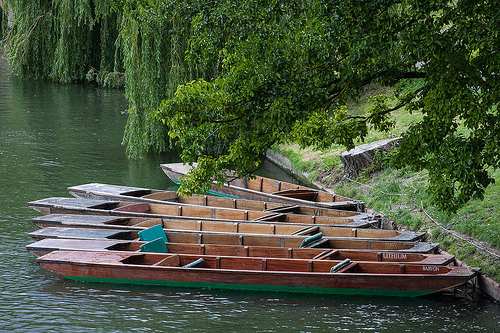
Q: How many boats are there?
A: 7.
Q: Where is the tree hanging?
A: Behind the boats.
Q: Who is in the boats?
A: No one.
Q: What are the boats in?
A: Water.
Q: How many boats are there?
A: Seven.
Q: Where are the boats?
A: In the water.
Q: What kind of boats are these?
A: Rowing.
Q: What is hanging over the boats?
A: A tree branch.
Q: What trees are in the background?
A: Weeping willows.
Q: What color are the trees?
A: Green.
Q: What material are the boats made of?
A: Wood.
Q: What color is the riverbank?
A: Green.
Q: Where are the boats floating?
A: In water.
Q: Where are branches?
A: On the trees.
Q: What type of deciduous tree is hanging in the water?
A: A willow tree.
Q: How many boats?
A: Seven.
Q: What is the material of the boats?
A: Wood.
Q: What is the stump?
A: A tree trunk.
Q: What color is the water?
A: Green.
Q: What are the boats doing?
A: Floating.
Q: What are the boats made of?
A: Wood.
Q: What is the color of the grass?
A: Greens.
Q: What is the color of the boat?
A: Brown.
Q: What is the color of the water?
A: Dark green.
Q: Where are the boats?
A: On the water.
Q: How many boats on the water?
A: Seven.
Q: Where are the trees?
A: By the river.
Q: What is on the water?
A: Boats.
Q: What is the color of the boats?
A: Brown.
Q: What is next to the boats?
A: Tree.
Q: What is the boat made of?
A: Wood.